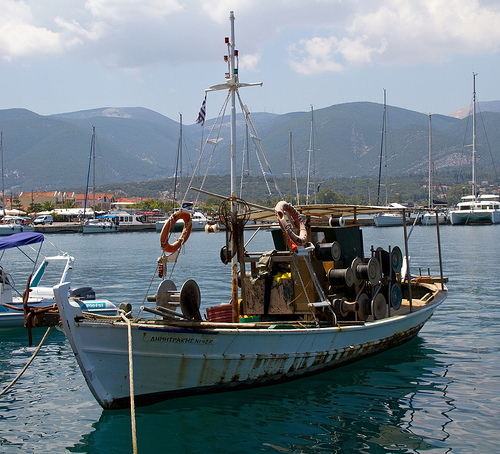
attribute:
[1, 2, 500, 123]
sky — cloudy, clear, blue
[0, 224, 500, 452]
water — see through, clear, blue, calm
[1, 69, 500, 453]
boats — grouped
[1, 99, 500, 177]
moutains — far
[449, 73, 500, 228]
boat — white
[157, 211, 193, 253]
lifesaver — red, orange, round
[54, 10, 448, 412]
boat — rusty, tethered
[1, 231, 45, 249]
roof — purple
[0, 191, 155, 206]
roofs — orange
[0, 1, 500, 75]
clouds — white, fluffy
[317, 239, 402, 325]
spools — empty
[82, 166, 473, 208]
trees — green, far